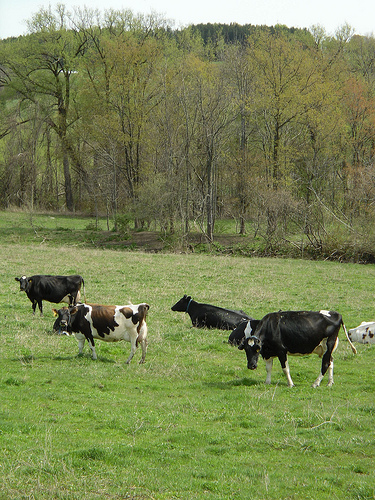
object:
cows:
[14, 275, 373, 387]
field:
[2, 225, 374, 500]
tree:
[196, 91, 229, 245]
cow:
[15, 272, 83, 316]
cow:
[52, 301, 149, 366]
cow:
[237, 307, 359, 389]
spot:
[247, 339, 255, 348]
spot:
[318, 309, 330, 318]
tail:
[341, 323, 355, 358]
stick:
[40, 233, 50, 245]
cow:
[170, 296, 255, 332]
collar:
[184, 297, 192, 313]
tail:
[81, 281, 88, 304]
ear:
[51, 308, 61, 318]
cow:
[226, 319, 263, 347]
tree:
[237, 43, 356, 241]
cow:
[346, 319, 373, 345]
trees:
[6, 1, 374, 239]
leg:
[123, 331, 138, 367]